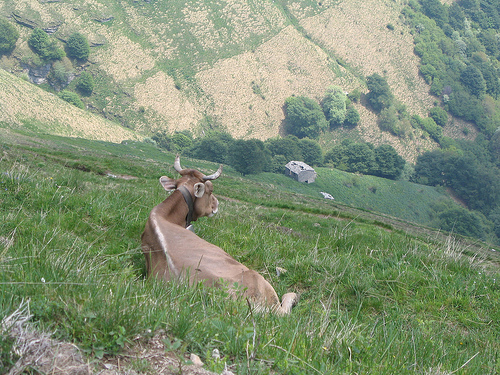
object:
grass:
[0, 120, 499, 374]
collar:
[178, 183, 200, 229]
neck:
[160, 187, 198, 230]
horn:
[202, 164, 224, 180]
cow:
[138, 153, 296, 320]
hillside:
[0, 0, 498, 177]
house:
[282, 158, 316, 184]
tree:
[322, 84, 345, 127]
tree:
[364, 73, 394, 115]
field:
[0, 128, 499, 373]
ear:
[192, 181, 205, 198]